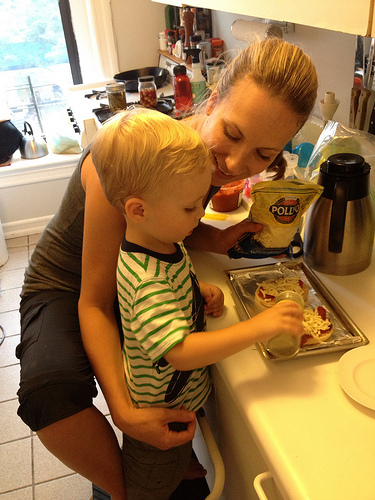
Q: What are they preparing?
A: Pizza.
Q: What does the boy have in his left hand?
A: Cheese.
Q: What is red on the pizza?
A: Sauce.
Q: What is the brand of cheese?
A: Polly-O.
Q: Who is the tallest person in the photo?
A: The mother.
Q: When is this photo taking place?
A: Daytime.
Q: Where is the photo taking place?
A: A kitchen.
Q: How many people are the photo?
A: Two.